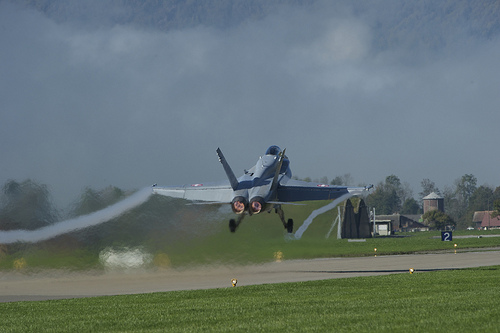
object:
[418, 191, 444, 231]
silo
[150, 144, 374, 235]
plane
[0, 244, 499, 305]
runway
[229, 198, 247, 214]
burners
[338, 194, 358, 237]
sheds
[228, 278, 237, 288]
lights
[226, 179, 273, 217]
tail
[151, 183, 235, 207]
wing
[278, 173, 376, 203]
wing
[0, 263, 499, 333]
grass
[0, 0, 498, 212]
clouds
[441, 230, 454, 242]
sign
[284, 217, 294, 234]
wheels